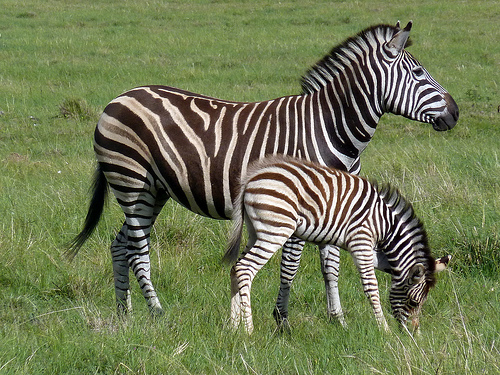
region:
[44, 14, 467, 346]
A pair of zebras in a grassy field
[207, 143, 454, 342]
The zebra is eating grass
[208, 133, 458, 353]
The small zebra is striped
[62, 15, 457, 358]
The zebras are black and white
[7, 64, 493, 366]
The grass is tall and green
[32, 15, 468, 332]
The big zebra is black and white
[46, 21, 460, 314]
The big zebra has black and white stripes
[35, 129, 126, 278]
The big zebra's tail hangs low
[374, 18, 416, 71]
The big zebra's ears are pointed up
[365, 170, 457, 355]
The small zebra is looking at the grass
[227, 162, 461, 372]
baby zebra is eating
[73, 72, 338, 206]
a brown and white fur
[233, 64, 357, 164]
a brown and white fur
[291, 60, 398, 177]
a brown and white fur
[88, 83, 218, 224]
a brown and white fur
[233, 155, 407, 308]
a brown and white fur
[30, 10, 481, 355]
two animals in a field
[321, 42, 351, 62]
zebra's mane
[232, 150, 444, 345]
young zebra with head down, grazing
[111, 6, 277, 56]
short green grass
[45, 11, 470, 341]
one adult zebra and one foal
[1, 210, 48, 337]
brown and green foliage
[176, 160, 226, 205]
stripes along an animal's belly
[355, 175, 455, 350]
a foal, head down, feeding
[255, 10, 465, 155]
adult zebra with head erect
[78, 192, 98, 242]
zebra's black tail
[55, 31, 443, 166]
Large zebra in field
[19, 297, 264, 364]
Tall green grass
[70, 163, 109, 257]
black zebra tail swinging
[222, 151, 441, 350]
Baby zebra eating grass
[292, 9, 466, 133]
Head of big zebra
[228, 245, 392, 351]
four legs of baby zebra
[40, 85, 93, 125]
bunch of weeds in field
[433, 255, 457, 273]
Baby zebra ear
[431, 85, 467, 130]
Black nose of zebra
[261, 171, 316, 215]
Brown and white stripes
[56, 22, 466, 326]
Brown and white zebra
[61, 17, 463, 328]
Brown and white zebra next to small zebra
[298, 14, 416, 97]
Black and white mane on zebra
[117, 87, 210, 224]
Large brown stripe on zebra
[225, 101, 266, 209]
Large brown stripe on zebra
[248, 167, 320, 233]
Large brown stripe on zebra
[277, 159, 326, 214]
Large brown stripe on zebra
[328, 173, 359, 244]
Large brown stripe on zebra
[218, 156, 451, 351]
Small zebra is grazing